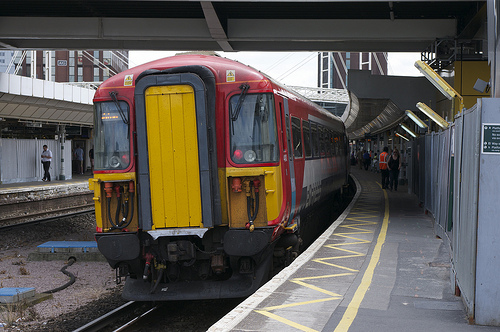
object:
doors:
[287, 102, 296, 225]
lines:
[292, 270, 352, 283]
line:
[332, 226, 376, 291]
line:
[244, 186, 402, 332]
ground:
[274, 161, 430, 327]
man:
[378, 147, 390, 189]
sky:
[265, 58, 305, 83]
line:
[313, 252, 363, 262]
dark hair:
[43, 145, 48, 148]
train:
[88, 47, 352, 308]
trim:
[288, 149, 363, 184]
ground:
[0, 206, 124, 329]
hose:
[40, 258, 76, 294]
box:
[37, 240, 100, 253]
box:
[1, 284, 32, 303]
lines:
[311, 259, 360, 272]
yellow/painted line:
[323, 245, 362, 255]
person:
[387, 148, 401, 192]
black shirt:
[389, 156, 400, 169]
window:
[226, 87, 279, 164]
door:
[142, 87, 202, 227]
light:
[244, 150, 257, 162]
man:
[41, 144, 53, 181]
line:
[358, 201, 389, 302]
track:
[67, 282, 235, 332]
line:
[326, 240, 369, 246]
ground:
[0, 218, 452, 330]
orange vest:
[379, 152, 389, 170]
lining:
[198, 119, 208, 169]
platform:
[0, 172, 100, 233]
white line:
[212, 197, 355, 329]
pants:
[40, 161, 51, 181]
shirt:
[41, 150, 52, 161]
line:
[257, 297, 339, 311]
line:
[291, 278, 337, 296]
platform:
[230, 158, 471, 330]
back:
[83, 54, 297, 306]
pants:
[380, 169, 390, 188]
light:
[413, 60, 465, 112]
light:
[416, 102, 450, 128]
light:
[405, 110, 430, 133]